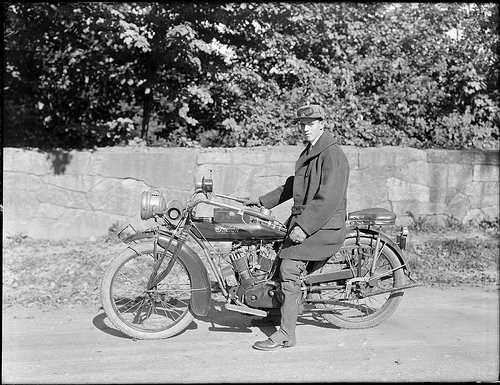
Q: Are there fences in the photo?
A: No, there are no fences.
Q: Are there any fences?
A: No, there are no fences.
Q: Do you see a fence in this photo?
A: No, there are no fences.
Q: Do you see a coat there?
A: Yes, there is a coat.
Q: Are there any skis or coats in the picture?
A: Yes, there is a coat.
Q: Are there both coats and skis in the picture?
A: No, there is a coat but no skis.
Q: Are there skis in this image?
A: No, there are no skis.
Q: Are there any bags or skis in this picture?
A: No, there are no skis or bags.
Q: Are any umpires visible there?
A: No, there are no umpires.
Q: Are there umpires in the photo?
A: No, there are no umpires.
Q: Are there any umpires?
A: No, there are no umpires.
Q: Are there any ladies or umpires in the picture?
A: No, there are no umpires or ladies.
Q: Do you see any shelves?
A: No, there are no shelves.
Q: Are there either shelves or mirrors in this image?
A: No, there are no shelves or mirrors.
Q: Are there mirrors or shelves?
A: No, there are no shelves or mirrors.